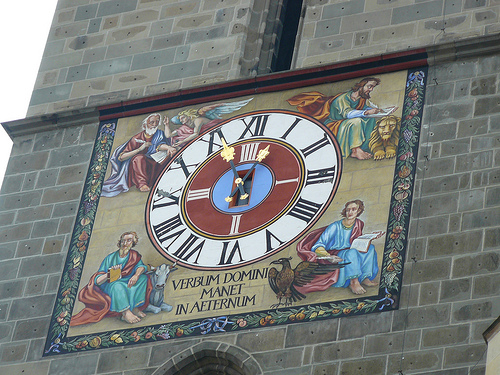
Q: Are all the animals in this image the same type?
A: No, they are lions and birds.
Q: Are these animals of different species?
A: Yes, they are lions and birds.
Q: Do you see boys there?
A: No, there are no boys.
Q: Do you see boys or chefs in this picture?
A: No, there are no boys or chefs.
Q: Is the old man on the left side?
A: Yes, the man is on the left of the image.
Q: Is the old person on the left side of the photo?
A: Yes, the man is on the left of the image.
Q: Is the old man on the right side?
A: No, the man is on the left of the image.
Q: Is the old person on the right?
A: No, the man is on the left of the image.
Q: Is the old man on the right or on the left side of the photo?
A: The man is on the left of the image.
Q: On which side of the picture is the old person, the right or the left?
A: The man is on the left of the image.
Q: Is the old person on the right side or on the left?
A: The man is on the left of the image.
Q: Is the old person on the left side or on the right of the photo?
A: The man is on the left of the image.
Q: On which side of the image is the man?
A: The man is on the left of the image.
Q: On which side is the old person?
A: The man is on the left of the image.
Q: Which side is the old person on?
A: The man is on the left of the image.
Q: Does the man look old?
A: Yes, the man is old.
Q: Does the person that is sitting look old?
A: Yes, the man is old.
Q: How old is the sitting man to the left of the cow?
A: The man is old.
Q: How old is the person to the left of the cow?
A: The man is old.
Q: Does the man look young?
A: No, the man is old.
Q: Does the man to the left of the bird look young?
A: No, the man is old.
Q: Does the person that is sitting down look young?
A: No, the man is old.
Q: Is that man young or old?
A: The man is old.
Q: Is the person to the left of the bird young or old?
A: The man is old.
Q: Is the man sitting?
A: Yes, the man is sitting.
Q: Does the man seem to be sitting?
A: Yes, the man is sitting.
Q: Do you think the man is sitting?
A: Yes, the man is sitting.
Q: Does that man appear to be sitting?
A: Yes, the man is sitting.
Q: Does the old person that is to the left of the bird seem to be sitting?
A: Yes, the man is sitting.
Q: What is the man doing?
A: The man is sitting.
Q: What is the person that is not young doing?
A: The man is sitting.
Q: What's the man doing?
A: The man is sitting.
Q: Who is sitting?
A: The man is sitting.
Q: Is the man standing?
A: No, the man is sitting.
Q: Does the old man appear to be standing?
A: No, the man is sitting.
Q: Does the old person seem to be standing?
A: No, the man is sitting.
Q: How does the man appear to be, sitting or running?
A: The man is sitting.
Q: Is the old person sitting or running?
A: The man is sitting.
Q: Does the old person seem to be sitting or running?
A: The man is sitting.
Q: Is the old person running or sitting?
A: The man is sitting.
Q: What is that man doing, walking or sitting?
A: The man is sitting.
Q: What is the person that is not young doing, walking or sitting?
A: The man is sitting.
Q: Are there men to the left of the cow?
A: Yes, there is a man to the left of the cow.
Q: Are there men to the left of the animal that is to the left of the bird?
A: Yes, there is a man to the left of the cow.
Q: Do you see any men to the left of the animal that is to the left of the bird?
A: Yes, there is a man to the left of the cow.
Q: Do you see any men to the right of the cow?
A: No, the man is to the left of the cow.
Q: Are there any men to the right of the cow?
A: No, the man is to the left of the cow.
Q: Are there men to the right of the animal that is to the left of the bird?
A: No, the man is to the left of the cow.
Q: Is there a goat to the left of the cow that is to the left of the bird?
A: No, there is a man to the left of the cow.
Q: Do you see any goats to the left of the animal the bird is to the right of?
A: No, there is a man to the left of the cow.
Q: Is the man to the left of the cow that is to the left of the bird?
A: Yes, the man is to the left of the cow.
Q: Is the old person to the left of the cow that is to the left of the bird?
A: Yes, the man is to the left of the cow.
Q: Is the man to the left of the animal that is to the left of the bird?
A: Yes, the man is to the left of the cow.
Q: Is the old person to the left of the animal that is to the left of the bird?
A: Yes, the man is to the left of the cow.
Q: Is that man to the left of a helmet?
A: No, the man is to the left of the cow.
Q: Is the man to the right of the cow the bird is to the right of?
A: No, the man is to the left of the cow.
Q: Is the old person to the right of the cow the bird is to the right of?
A: No, the man is to the left of the cow.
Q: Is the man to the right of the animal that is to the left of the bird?
A: No, the man is to the left of the cow.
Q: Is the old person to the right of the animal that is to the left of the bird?
A: No, the man is to the left of the cow.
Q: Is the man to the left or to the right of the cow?
A: The man is to the left of the cow.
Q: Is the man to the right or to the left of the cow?
A: The man is to the left of the cow.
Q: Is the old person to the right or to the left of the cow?
A: The man is to the left of the cow.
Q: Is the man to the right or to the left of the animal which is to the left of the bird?
A: The man is to the left of the cow.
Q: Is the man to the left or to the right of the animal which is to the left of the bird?
A: The man is to the left of the cow.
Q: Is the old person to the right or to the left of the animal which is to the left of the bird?
A: The man is to the left of the cow.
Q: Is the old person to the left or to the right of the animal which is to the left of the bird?
A: The man is to the left of the cow.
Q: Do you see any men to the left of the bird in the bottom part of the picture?
A: Yes, there is a man to the left of the bird.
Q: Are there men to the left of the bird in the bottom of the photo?
A: Yes, there is a man to the left of the bird.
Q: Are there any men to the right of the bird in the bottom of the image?
A: No, the man is to the left of the bird.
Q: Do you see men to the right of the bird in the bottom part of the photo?
A: No, the man is to the left of the bird.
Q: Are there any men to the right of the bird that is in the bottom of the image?
A: No, the man is to the left of the bird.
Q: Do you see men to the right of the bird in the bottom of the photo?
A: No, the man is to the left of the bird.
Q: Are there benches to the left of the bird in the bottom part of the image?
A: No, there is a man to the left of the bird.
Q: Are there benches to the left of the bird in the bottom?
A: No, there is a man to the left of the bird.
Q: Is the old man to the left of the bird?
A: Yes, the man is to the left of the bird.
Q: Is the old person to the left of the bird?
A: Yes, the man is to the left of the bird.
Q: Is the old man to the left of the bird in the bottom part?
A: Yes, the man is to the left of the bird.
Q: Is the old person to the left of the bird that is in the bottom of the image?
A: Yes, the man is to the left of the bird.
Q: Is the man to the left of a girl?
A: No, the man is to the left of the bird.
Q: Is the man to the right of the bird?
A: No, the man is to the left of the bird.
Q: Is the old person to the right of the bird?
A: No, the man is to the left of the bird.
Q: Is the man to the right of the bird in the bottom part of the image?
A: No, the man is to the left of the bird.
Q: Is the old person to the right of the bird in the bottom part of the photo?
A: No, the man is to the left of the bird.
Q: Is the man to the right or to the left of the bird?
A: The man is to the left of the bird.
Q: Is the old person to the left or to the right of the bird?
A: The man is to the left of the bird.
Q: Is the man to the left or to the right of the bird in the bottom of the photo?
A: The man is to the left of the bird.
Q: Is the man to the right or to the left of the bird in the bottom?
A: The man is to the left of the bird.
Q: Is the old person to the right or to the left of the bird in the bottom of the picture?
A: The man is to the left of the bird.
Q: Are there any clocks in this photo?
A: Yes, there is a clock.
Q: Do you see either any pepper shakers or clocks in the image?
A: Yes, there is a clock.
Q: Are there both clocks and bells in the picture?
A: No, there is a clock but no bells.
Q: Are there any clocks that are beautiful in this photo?
A: Yes, there is a beautiful clock.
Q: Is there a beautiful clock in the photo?
A: Yes, there is a beautiful clock.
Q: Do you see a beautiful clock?
A: Yes, there is a beautiful clock.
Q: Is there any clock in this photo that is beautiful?
A: Yes, there is a clock that is beautiful.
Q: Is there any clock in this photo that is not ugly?
A: Yes, there is an beautiful clock.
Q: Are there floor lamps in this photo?
A: No, there are no floor lamps.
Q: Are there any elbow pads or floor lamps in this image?
A: No, there are no floor lamps or elbow pads.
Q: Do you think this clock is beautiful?
A: Yes, the clock is beautiful.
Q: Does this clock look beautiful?
A: Yes, the clock is beautiful.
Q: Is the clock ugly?
A: No, the clock is beautiful.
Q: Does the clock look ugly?
A: No, the clock is beautiful.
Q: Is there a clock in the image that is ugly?
A: No, there is a clock but it is beautiful.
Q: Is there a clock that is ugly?
A: No, there is a clock but it is beautiful.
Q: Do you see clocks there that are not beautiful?
A: No, there is a clock but it is beautiful.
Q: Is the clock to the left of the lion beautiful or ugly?
A: The clock is beautiful.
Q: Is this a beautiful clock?
A: Yes, this is a beautiful clock.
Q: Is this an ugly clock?
A: No, this is a beautiful clock.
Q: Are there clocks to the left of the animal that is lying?
A: Yes, there is a clock to the left of the lion.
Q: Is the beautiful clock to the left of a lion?
A: Yes, the clock is to the left of a lion.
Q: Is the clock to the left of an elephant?
A: No, the clock is to the left of a lion.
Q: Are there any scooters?
A: No, there are no scooters.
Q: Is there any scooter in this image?
A: No, there are no scooters.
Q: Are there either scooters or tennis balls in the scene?
A: No, there are no scooters or tennis balls.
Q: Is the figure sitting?
A: Yes, the figure is sitting.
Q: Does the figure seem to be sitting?
A: Yes, the figure is sitting.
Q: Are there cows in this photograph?
A: Yes, there is a cow.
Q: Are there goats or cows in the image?
A: Yes, there is a cow.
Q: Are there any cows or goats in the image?
A: Yes, there is a cow.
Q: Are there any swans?
A: No, there are no swans.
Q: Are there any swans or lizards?
A: No, there are no swans or lizards.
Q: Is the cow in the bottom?
A: Yes, the cow is in the bottom of the image.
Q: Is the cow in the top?
A: No, the cow is in the bottom of the image.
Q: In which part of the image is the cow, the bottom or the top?
A: The cow is in the bottom of the image.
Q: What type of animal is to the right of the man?
A: The animal is a cow.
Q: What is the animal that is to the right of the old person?
A: The animal is a cow.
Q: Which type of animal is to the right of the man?
A: The animal is a cow.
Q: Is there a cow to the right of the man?
A: Yes, there is a cow to the right of the man.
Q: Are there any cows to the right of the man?
A: Yes, there is a cow to the right of the man.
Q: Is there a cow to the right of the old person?
A: Yes, there is a cow to the right of the man.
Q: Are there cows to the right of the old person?
A: Yes, there is a cow to the right of the man.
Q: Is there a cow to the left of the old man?
A: No, the cow is to the right of the man.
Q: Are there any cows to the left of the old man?
A: No, the cow is to the right of the man.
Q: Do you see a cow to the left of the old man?
A: No, the cow is to the right of the man.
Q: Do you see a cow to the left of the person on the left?
A: No, the cow is to the right of the man.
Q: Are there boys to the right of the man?
A: No, there is a cow to the right of the man.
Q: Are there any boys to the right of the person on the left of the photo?
A: No, there is a cow to the right of the man.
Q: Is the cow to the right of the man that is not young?
A: Yes, the cow is to the right of the man.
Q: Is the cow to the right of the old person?
A: Yes, the cow is to the right of the man.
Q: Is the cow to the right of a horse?
A: No, the cow is to the right of the man.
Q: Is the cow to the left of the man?
A: No, the cow is to the right of the man.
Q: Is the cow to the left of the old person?
A: No, the cow is to the right of the man.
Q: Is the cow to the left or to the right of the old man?
A: The cow is to the right of the man.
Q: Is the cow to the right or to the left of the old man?
A: The cow is to the right of the man.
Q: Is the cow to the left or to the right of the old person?
A: The cow is to the right of the man.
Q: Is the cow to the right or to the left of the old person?
A: The cow is to the right of the man.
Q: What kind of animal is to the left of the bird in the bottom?
A: The animal is a cow.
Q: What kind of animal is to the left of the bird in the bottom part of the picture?
A: The animal is a cow.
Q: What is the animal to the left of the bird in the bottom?
A: The animal is a cow.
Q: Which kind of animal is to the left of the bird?
A: The animal is a cow.